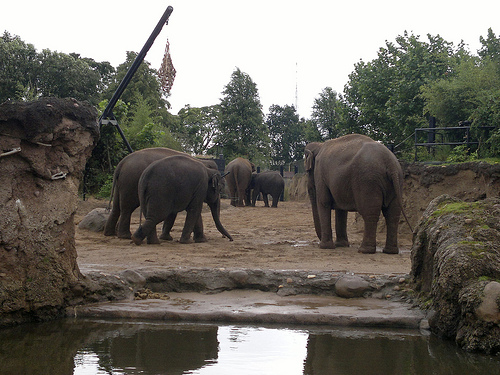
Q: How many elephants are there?
A: Five.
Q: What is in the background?
A: Forest.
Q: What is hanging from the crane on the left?
A: A net.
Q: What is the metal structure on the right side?
A: A fence.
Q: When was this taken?
A: During the day.